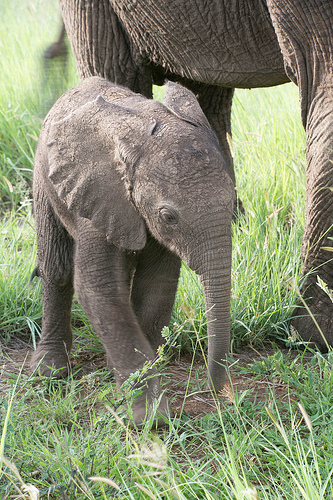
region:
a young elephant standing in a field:
[8, 96, 250, 382]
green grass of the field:
[213, 422, 293, 487]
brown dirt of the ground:
[167, 355, 198, 410]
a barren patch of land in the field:
[0, 319, 329, 424]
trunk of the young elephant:
[177, 247, 237, 401]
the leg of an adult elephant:
[277, 79, 329, 352]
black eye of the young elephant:
[154, 204, 182, 235]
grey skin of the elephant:
[151, 128, 197, 182]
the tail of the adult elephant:
[29, 14, 97, 75]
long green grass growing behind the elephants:
[253, 104, 304, 180]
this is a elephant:
[48, 92, 212, 485]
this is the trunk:
[197, 235, 239, 391]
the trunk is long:
[202, 264, 234, 375]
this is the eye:
[159, 202, 182, 231]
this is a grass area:
[100, 439, 317, 494]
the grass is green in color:
[194, 456, 328, 493]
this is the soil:
[186, 397, 197, 405]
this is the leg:
[89, 284, 161, 360]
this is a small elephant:
[34, 78, 243, 428]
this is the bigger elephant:
[135, 0, 321, 63]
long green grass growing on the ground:
[65, 407, 302, 483]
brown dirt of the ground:
[173, 370, 230, 414]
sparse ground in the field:
[4, 317, 277, 433]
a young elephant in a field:
[28, 100, 226, 374]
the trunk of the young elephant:
[177, 230, 241, 384]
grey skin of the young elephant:
[65, 130, 115, 189]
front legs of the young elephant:
[86, 261, 180, 423]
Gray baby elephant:
[30, 76, 246, 424]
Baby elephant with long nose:
[18, 78, 241, 426]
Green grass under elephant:
[41, 409, 149, 496]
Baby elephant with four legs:
[33, 80, 231, 422]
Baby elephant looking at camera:
[34, 67, 249, 454]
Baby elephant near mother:
[26, 70, 261, 432]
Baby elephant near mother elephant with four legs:
[61, 2, 332, 371]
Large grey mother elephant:
[264, 1, 331, 355]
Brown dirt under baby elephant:
[174, 378, 211, 416]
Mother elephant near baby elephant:
[275, 0, 330, 367]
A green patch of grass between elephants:
[154, 86, 161, 95]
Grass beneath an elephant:
[239, 245, 293, 296]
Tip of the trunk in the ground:
[206, 380, 226, 392]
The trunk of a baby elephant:
[206, 255, 230, 392]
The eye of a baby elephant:
[159, 208, 177, 225]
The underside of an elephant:
[202, 64, 281, 80]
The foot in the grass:
[235, 210, 246, 222]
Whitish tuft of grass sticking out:
[141, 452, 167, 466]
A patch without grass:
[189, 401, 202, 413]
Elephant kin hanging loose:
[299, 52, 317, 91]